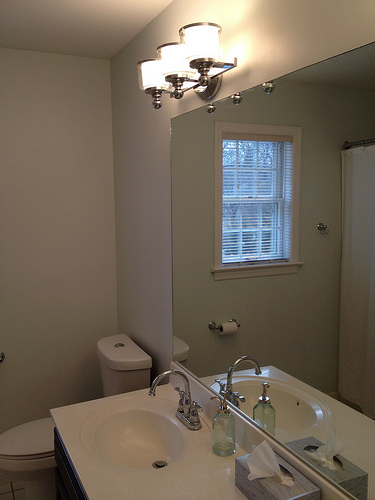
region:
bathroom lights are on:
[101, 21, 291, 146]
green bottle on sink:
[191, 387, 254, 459]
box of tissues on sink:
[232, 447, 322, 496]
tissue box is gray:
[213, 440, 308, 496]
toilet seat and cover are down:
[1, 402, 96, 468]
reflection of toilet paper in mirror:
[202, 306, 292, 355]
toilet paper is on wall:
[183, 303, 248, 337]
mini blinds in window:
[220, 134, 289, 260]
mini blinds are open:
[220, 134, 301, 259]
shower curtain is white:
[337, 143, 372, 393]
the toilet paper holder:
[208, 319, 240, 336]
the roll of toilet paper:
[220, 320, 235, 329]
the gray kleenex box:
[234, 443, 319, 496]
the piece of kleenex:
[251, 444, 273, 474]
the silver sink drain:
[153, 457, 163, 467]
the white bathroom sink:
[90, 399, 183, 467]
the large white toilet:
[8, 330, 143, 482]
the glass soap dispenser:
[210, 390, 233, 452]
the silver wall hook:
[316, 223, 326, 232]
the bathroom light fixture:
[137, 23, 237, 98]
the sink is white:
[71, 391, 177, 498]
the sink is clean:
[65, 405, 211, 491]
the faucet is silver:
[144, 360, 199, 411]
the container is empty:
[208, 413, 235, 460]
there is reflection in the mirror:
[198, 321, 370, 422]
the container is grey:
[228, 457, 308, 499]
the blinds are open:
[227, 119, 299, 256]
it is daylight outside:
[227, 140, 292, 255]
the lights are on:
[132, 35, 226, 84]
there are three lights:
[129, 34, 230, 87]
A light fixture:
[129, 12, 242, 106]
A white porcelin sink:
[77, 401, 185, 482]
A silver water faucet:
[150, 362, 203, 432]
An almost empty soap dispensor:
[200, 385, 239, 462]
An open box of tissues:
[230, 436, 327, 499]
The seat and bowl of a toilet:
[0, 419, 58, 491]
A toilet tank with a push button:
[89, 319, 154, 391]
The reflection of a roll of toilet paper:
[206, 313, 248, 341]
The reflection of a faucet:
[221, 352, 266, 410]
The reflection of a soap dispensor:
[254, 380, 274, 434]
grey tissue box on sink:
[235, 444, 327, 496]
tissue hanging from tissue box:
[244, 437, 293, 479]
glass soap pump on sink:
[210, 389, 235, 457]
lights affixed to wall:
[137, 19, 227, 112]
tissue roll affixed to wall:
[218, 320, 239, 335]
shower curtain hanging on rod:
[338, 145, 373, 393]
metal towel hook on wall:
[317, 222, 329, 237]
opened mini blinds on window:
[221, 136, 296, 260]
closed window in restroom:
[223, 138, 293, 261]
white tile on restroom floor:
[0, 480, 26, 498]